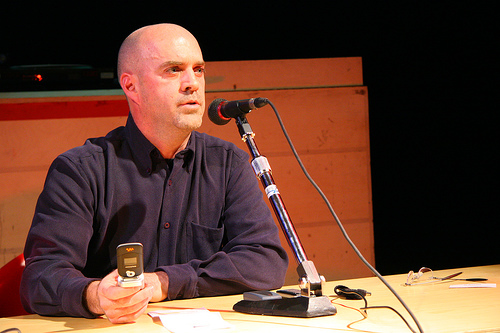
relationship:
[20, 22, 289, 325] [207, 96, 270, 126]
man with microphone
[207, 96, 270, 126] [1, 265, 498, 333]
microphone on table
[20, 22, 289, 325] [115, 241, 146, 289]
man with cell phone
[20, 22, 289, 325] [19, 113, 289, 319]
man wearing shirt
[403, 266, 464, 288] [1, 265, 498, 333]
glasses on table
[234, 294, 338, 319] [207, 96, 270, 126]
base of microphone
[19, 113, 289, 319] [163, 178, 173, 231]
shirt with buttons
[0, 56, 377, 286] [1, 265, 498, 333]
bench behind table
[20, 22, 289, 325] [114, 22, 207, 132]
man without hair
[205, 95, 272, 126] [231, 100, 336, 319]
microphone on stand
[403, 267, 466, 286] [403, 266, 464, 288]
pair of glasses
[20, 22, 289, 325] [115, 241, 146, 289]
man holding cell phone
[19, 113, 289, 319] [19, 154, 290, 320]
shirt has long sleeves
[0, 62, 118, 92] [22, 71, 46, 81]
black box with red light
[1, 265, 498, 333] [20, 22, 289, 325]
table under man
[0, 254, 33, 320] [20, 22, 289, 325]
chair under man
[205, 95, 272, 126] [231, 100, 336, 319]
microphone in stand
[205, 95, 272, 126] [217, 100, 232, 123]
microphone with red band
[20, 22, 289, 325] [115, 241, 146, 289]
man holding flip phone